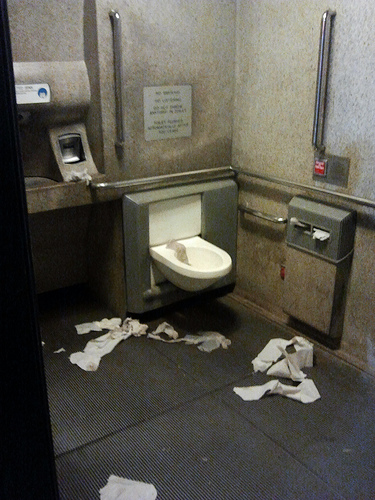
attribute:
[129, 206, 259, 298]
toilet — white, grey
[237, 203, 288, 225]
handrail — shiney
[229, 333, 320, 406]
toiletpaper — white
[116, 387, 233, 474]
floor — gray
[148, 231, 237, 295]
toilet — white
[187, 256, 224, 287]
bowl — white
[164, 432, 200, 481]
floor — black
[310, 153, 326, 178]
sign — red and white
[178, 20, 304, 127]
walls — beige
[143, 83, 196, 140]
sign — white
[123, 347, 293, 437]
floor — gray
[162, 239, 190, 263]
toilet paper — wet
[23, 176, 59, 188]
basin — white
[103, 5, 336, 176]
bars — silver